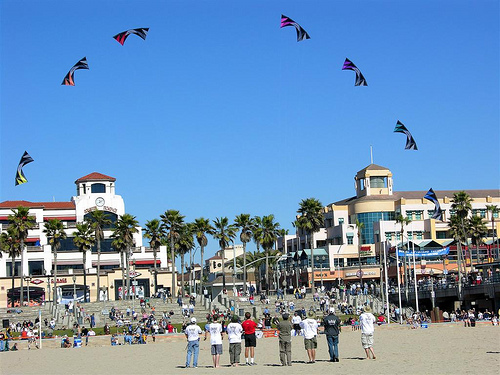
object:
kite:
[279, 12, 312, 44]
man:
[184, 316, 203, 369]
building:
[1, 171, 171, 303]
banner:
[397, 246, 449, 259]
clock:
[95, 197, 107, 208]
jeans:
[326, 331, 340, 361]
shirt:
[241, 319, 257, 335]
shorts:
[303, 336, 318, 351]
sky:
[2, 0, 498, 213]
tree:
[206, 217, 235, 296]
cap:
[326, 307, 337, 315]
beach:
[0, 321, 498, 375]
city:
[2, 149, 500, 338]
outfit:
[277, 319, 295, 366]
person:
[298, 310, 319, 364]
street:
[2, 282, 375, 305]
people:
[110, 299, 174, 336]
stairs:
[2, 291, 396, 327]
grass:
[8, 315, 362, 340]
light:
[380, 232, 392, 324]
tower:
[73, 171, 127, 225]